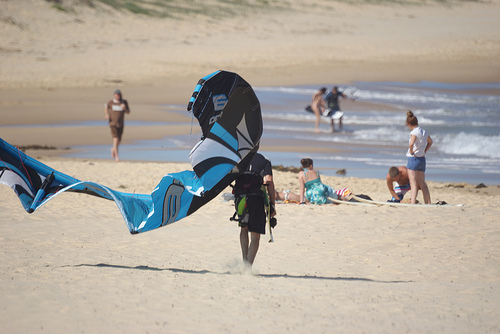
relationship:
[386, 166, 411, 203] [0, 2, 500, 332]
man kneeling in sand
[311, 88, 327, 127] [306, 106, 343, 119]
woman with surfboard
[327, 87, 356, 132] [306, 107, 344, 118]
man with surfboard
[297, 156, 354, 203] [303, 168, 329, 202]
woman wearing swimsuit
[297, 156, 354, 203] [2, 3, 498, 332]
woman sitting on beach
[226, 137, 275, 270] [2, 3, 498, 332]
man standing on beach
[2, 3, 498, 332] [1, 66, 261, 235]
beach has kite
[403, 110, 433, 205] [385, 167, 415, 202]
woman watching man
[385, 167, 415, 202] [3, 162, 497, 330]
man digging in sand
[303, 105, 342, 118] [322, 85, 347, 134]
surfboard between man